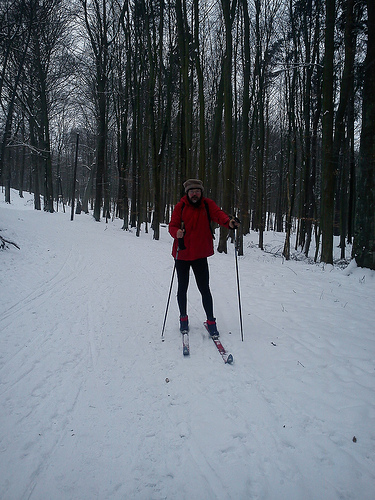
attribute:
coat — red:
[169, 195, 229, 258]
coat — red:
[164, 195, 233, 259]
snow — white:
[1, 184, 372, 499]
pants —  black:
[171, 253, 215, 323]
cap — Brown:
[183, 177, 205, 194]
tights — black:
[174, 257, 214, 319]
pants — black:
[160, 237, 264, 358]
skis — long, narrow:
[180, 322, 233, 363]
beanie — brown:
[175, 162, 220, 195]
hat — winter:
[182, 177, 203, 192]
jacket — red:
[169, 193, 232, 259]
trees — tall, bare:
[0, 0, 373, 271]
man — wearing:
[167, 177, 243, 337]